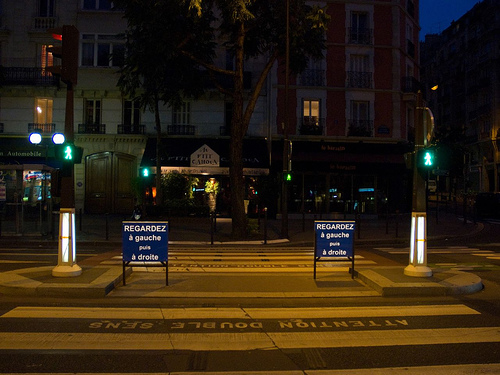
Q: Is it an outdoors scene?
A: Yes, it is outdoors.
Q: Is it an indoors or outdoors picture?
A: It is outdoors.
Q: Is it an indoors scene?
A: No, it is outdoors.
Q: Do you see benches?
A: No, there are no benches.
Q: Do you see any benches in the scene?
A: No, there are no benches.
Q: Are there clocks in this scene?
A: No, there are no clocks.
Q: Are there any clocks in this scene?
A: No, there are no clocks.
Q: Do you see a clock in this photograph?
A: No, there are no clocks.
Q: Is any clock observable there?
A: No, there are no clocks.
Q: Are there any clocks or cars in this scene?
A: No, there are no clocks or cars.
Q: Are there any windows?
A: Yes, there is a window.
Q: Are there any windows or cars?
A: Yes, there is a window.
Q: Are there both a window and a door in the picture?
A: Yes, there are both a window and a door.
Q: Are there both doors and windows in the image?
A: Yes, there are both a window and a door.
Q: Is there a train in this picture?
A: No, there are no trains.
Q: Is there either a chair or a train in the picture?
A: No, there are no trains or chairs.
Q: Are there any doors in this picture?
A: Yes, there is a door.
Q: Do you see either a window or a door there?
A: Yes, there is a door.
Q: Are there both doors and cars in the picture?
A: No, there is a door but no cars.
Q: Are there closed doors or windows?
A: Yes, there is a closed door.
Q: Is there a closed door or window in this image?
A: Yes, there is a closed door.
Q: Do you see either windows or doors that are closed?
A: Yes, the door is closed.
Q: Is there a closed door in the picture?
A: Yes, there is a closed door.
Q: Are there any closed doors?
A: Yes, there is a closed door.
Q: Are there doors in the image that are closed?
A: Yes, there is a door that is closed.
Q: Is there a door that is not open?
A: Yes, there is an closed door.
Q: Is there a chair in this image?
A: No, there are no chairs.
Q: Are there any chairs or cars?
A: No, there are no chairs or cars.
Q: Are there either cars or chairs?
A: No, there are no chairs or cars.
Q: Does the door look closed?
A: Yes, the door is closed.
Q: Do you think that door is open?
A: No, the door is closed.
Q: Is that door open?
A: No, the door is closed.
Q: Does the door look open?
A: No, the door is closed.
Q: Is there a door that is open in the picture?
A: No, there is a door but it is closed.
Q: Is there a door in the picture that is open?
A: No, there is a door but it is closed.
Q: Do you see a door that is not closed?
A: No, there is a door but it is closed.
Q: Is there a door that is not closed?
A: No, there is a door but it is closed.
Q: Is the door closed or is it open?
A: The door is closed.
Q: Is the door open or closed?
A: The door is closed.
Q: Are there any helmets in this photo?
A: No, there are no helmets.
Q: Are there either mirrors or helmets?
A: No, there are no helmets or mirrors.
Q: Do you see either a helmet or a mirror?
A: No, there are no helmets or mirrors.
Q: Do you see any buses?
A: No, there are no buses.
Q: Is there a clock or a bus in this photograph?
A: No, there are no buses or clocks.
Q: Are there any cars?
A: No, there are no cars.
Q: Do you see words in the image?
A: Yes, there are words.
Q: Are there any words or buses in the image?
A: Yes, there are words.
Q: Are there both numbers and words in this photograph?
A: No, there are words but no numbers.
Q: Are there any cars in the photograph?
A: No, there are no cars.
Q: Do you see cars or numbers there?
A: No, there are no cars or numbers.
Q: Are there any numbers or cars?
A: No, there are no cars or numbers.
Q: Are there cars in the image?
A: No, there are no cars.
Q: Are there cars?
A: No, there are no cars.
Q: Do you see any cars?
A: No, there are no cars.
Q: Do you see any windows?
A: Yes, there is a window.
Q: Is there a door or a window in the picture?
A: Yes, there is a window.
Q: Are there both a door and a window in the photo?
A: Yes, there are both a window and a door.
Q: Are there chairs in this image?
A: No, there are no chairs.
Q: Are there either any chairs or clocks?
A: No, there are no chairs or clocks.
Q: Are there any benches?
A: No, there are no benches.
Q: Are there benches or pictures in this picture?
A: No, there are no benches or pictures.